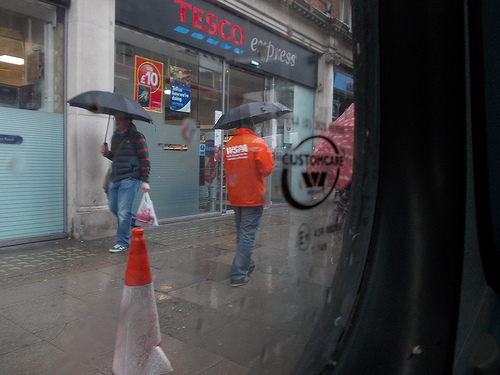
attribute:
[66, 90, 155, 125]
umbrella — black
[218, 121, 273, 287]
person — walking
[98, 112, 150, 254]
person — walking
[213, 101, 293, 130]
umbrella — black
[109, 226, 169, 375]
cone — orange, tall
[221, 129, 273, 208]
jacket — orange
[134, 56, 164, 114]
sign — poster, red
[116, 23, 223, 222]
window — glass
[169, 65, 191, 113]
sign — blue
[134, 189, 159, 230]
bag — white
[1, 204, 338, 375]
sidewalk — cement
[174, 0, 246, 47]
tescoe — named, red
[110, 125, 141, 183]
vest — grey